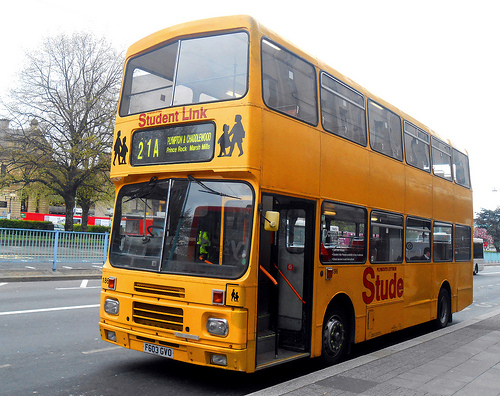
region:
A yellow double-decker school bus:
[97, 11, 489, 376]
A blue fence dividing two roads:
[0, 220, 122, 286]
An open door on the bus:
[246, 178, 321, 377]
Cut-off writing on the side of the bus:
[354, 262, 411, 308]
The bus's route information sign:
[122, 120, 216, 164]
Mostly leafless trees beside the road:
[7, 32, 109, 225]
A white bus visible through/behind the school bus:
[417, 232, 487, 274]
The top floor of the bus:
[107, 9, 498, 214]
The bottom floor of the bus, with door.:
[99, 177, 487, 376]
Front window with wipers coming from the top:
[104, 178, 254, 280]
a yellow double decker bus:
[57, 12, 494, 372]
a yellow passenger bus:
[97, 27, 497, 356]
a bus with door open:
[141, 72, 481, 387]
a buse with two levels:
[104, 32, 481, 395]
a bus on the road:
[44, 11, 371, 392]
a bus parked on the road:
[32, 13, 415, 394]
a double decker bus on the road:
[36, 14, 428, 395]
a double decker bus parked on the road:
[74, 7, 486, 394]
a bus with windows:
[92, 25, 476, 390]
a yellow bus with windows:
[102, 17, 499, 392]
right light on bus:
[198, 314, 236, 344]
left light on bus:
[89, 293, 129, 320]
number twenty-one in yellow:
[130, 135, 154, 162]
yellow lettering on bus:
[166, 131, 215, 155]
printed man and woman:
[215, 108, 244, 163]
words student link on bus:
[128, 104, 218, 122]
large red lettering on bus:
[357, 271, 411, 303]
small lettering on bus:
[375, 264, 399, 273]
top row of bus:
[282, 81, 437, 195]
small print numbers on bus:
[97, 272, 110, 287]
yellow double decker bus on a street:
[95, 8, 483, 374]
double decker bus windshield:
[105, 175, 246, 280]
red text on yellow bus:
[131, 105, 212, 125]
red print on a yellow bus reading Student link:
[131, 105, 211, 125]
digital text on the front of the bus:
[131, 125, 211, 160]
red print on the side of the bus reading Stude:
[350, 262, 402, 302]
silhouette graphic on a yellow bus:
[215, 110, 245, 157]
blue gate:
[0, 225, 110, 275]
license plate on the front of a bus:
[135, 340, 175, 355]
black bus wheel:
[315, 296, 364, 361]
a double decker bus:
[107, 25, 479, 347]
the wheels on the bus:
[313, 286, 455, 368]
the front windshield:
[110, 178, 250, 285]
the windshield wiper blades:
[115, 189, 241, 206]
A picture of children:
[218, 108, 246, 160]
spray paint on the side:
[390, 262, 442, 307]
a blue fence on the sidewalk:
[10, 226, 98, 269]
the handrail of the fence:
[0, 223, 106, 234]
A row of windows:
[259, 47, 475, 189]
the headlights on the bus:
[103, 294, 230, 344]